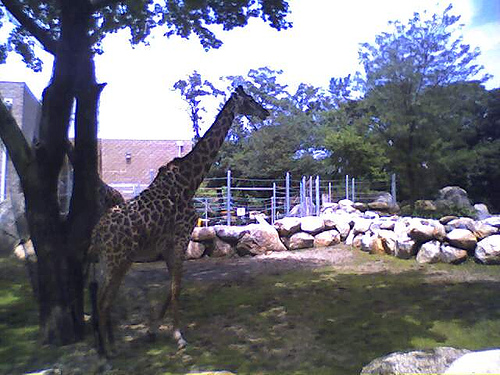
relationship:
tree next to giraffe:
[5, 8, 165, 355] [83, 83, 273, 363]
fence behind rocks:
[129, 168, 397, 225] [184, 186, 498, 373]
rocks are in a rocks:
[184, 186, 498, 373] [184, 185, 500, 266]